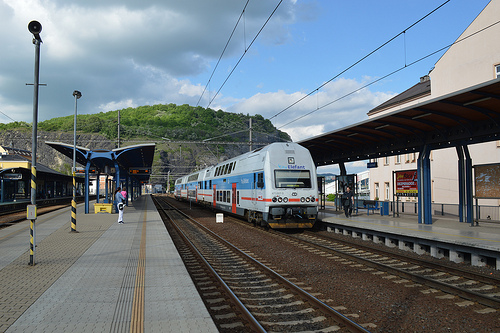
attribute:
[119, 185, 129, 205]
person — wearing pink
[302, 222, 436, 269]
tracks — train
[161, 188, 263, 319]
tracks — train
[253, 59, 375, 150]
clouds — grey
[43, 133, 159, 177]
roofs — curved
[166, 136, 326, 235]
train — blue, gray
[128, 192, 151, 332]
line — yellow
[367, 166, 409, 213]
window — yellow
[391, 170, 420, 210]
sign — elevated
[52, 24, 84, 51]
clouds — white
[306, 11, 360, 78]
sky — blue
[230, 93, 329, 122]
cloud — white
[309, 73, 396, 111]
cloud — white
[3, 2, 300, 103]
cloud — white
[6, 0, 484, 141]
sky — blue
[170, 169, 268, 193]
stripe — blue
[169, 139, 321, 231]
train — gray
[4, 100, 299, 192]
mountain — in distance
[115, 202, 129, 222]
pants — white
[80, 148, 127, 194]
supports — blue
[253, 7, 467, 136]
sky — blue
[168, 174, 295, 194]
stripes — blue, red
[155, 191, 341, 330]
tracks — train, not being used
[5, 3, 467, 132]
sky — blue